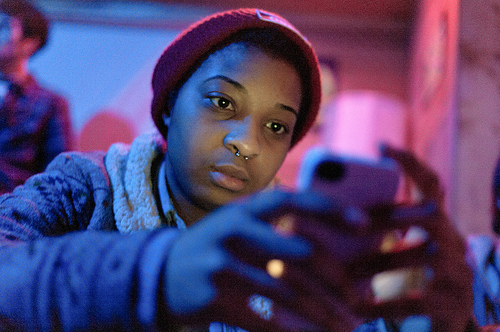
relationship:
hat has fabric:
[150, 8, 323, 152] [150, 7, 323, 149]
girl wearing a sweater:
[1, 7, 476, 331] [1, 128, 387, 331]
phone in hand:
[270, 147, 400, 331] [169, 188, 362, 331]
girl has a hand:
[1, 7, 476, 331] [169, 188, 362, 331]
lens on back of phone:
[310, 157, 350, 183] [270, 147, 400, 331]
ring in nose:
[234, 149, 250, 163] [222, 119, 261, 157]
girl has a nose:
[1, 7, 476, 331] [222, 119, 261, 157]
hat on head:
[150, 8, 323, 152] [167, 27, 303, 209]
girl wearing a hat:
[1, 7, 476, 331] [150, 8, 323, 152]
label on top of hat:
[255, 6, 312, 47] [150, 8, 323, 152]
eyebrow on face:
[203, 72, 248, 96] [166, 44, 303, 210]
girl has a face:
[1, 7, 476, 331] [166, 44, 303, 210]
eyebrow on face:
[274, 100, 301, 119] [166, 44, 303, 210]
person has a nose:
[1, 7, 476, 331] [222, 119, 261, 157]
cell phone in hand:
[270, 147, 400, 331] [169, 188, 362, 331]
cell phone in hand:
[270, 147, 400, 331] [347, 142, 477, 331]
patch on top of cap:
[255, 6, 312, 47] [150, 8, 323, 152]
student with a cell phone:
[1, 7, 476, 331] [270, 147, 400, 331]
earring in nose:
[234, 149, 250, 163] [222, 119, 261, 157]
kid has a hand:
[1, 7, 476, 331] [169, 188, 362, 331]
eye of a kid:
[263, 119, 290, 135] [1, 7, 476, 331]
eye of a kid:
[207, 94, 237, 114] [1, 7, 476, 331]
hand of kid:
[347, 142, 477, 331] [1, 7, 476, 331]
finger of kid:
[261, 186, 371, 233] [1, 7, 476, 331]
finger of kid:
[375, 140, 441, 195] [1, 7, 476, 331]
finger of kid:
[268, 225, 361, 307] [1, 7, 476, 331]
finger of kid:
[249, 263, 341, 332] [1, 7, 476, 331]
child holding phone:
[1, 7, 476, 331] [270, 147, 400, 331]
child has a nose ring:
[1, 7, 476, 331] [234, 149, 250, 163]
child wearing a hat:
[1, 7, 476, 331] [150, 8, 323, 152]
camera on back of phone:
[310, 157, 350, 183] [270, 147, 400, 331]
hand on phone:
[169, 188, 362, 331] [270, 147, 400, 331]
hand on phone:
[347, 142, 477, 331] [270, 147, 400, 331]